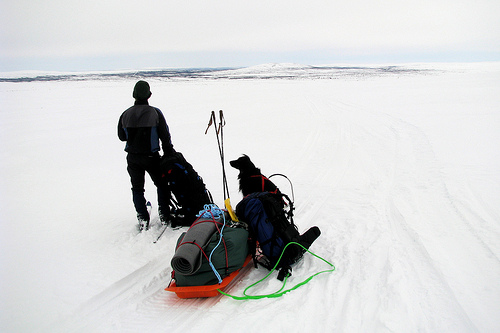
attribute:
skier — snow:
[114, 78, 176, 238]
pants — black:
[122, 153, 176, 227]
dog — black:
[227, 153, 279, 194]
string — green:
[228, 247, 364, 307]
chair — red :
[162, 258, 241, 303]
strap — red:
[253, 173, 279, 193]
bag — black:
[160, 151, 211, 218]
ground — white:
[316, 112, 486, 249]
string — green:
[216, 217, 400, 304]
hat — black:
[131, 75, 161, 100]